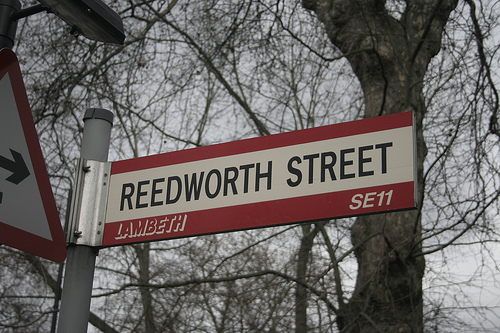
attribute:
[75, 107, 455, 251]
sign — striped, red, white, screwed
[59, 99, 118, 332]
pole — gray, metal, cracked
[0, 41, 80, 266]
sign — three sided, pointed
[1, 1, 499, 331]
trees — bare, tall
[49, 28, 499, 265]
sky — cloudy